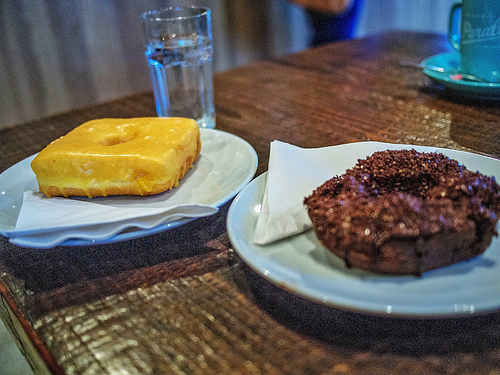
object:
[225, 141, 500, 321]
plate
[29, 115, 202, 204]
doughnut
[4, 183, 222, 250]
napkin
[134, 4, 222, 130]
glass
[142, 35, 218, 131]
water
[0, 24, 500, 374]
table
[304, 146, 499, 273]
chocolate donut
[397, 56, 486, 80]
utensil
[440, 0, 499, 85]
mug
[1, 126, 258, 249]
plate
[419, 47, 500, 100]
plate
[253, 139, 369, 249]
napkin